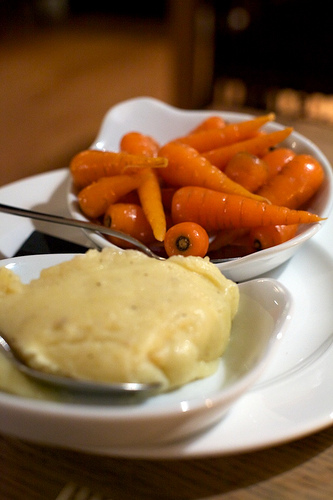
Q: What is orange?
A: Carrots.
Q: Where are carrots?
A: In a bowl.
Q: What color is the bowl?
A: White.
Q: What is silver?
A: Spoon.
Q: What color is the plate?
A: White.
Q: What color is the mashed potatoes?
A: White.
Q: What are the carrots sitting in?
A: Bowl.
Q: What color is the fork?
A: Silver.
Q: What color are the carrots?
A: Orange.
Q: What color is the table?
A: Brown.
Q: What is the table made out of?
A: Wood.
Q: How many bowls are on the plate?
A: Two.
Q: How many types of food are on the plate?
A: Two.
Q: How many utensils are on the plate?
A: Two.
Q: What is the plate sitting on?
A: Table.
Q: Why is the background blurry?
A: Out of focus.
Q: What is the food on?
A: Plate.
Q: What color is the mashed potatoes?
A: White.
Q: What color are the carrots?
A: Orange.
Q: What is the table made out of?
A: Wood.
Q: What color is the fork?
A: Silver.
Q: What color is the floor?
A: Brown.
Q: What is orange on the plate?
A: Carrots.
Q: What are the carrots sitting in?
A: Bowl.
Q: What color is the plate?
A: White.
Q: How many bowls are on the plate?
A: Two.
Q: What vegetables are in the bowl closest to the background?
A: Carrots.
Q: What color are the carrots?
A: Orange.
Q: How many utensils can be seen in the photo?
A: Two.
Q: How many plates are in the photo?
A: One.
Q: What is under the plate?
A: A table.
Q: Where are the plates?
A: On the table.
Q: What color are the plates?
A: White.